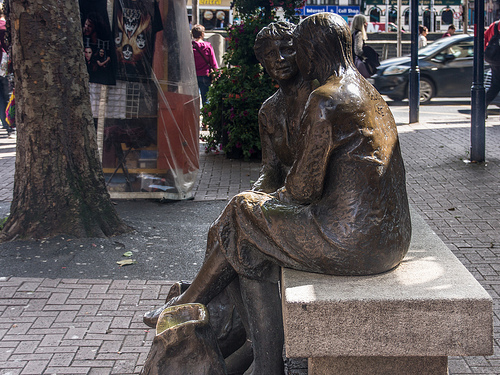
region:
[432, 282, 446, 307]
part of a bench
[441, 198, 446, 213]
part of a path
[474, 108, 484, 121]
part of a post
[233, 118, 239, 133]
part of a bush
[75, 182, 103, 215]
part of a stem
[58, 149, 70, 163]
edge of a stem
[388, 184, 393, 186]
back of a man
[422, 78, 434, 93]
part of a wheel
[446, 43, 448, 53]
part of a mirror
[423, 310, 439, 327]
part of a bench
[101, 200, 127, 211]
part of a stem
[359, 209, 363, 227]
back of a sculpture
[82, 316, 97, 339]
edge of a road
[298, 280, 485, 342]
stone seat in the square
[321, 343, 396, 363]
edge of stone seat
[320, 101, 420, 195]
sunshine reflecting on the statue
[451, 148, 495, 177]
white paper on ground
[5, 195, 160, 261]
large trunk on tree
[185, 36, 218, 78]
purse strap around woman's shoulder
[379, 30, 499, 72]
blue car on the street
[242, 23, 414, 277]
pair of statues on the bench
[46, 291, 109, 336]
stone bricks on the ground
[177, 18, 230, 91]
woman walking on the sidewalk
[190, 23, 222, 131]
woman wearing purple shirt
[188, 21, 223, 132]
woman carrying black crossbody purse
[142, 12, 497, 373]
statue of two people sitting on bench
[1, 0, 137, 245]
bottom of tree trunk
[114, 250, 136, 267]
leaves on the ground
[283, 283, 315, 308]
sun shining on bench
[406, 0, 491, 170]
part of two metal poles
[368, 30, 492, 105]
part of black car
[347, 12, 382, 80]
woman carring gray bag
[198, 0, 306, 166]
plants with purple and orange flowers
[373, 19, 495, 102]
car on the road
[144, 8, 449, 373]
statue on the sidewalk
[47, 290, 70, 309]
brick in the sidewalk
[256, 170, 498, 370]
bench on the sidewalk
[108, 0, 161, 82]
black shirt for sale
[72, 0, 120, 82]
black shirt for sale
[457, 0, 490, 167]
pole in the sidewalk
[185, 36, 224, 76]
woman in a purple shirt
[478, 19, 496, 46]
man in a red shirt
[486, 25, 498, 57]
man with a backpack